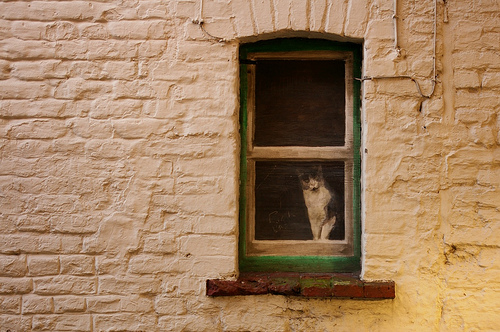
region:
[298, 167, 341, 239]
Gray and white cat in window area.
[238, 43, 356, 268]
Green color framing window.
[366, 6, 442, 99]
Cable cords along side of wall.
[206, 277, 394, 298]
Red bricks under the window.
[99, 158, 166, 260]
Repaired part of brick wall.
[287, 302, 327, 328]
Damage on stone wall.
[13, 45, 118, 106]
Old beige brick wall.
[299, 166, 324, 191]
Cat's face does not look real.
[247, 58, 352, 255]
Beige wooden border frame.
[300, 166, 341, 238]
Cat with gray eyes.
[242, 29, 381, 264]
The window is closed.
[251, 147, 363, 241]
The cat is in the window.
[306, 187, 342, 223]
The cat's fur is black and white.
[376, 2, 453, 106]
Pipes are seen on the outside of building.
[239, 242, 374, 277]
The edge of the window is green.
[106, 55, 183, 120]
Bricks of building have been painted beige.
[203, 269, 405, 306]
The window sill is made out of bricks.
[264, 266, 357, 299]
Bricks have green paint on them.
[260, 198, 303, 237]
The window is scratched.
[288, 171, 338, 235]
cat looking out the window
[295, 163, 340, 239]
gray and white cat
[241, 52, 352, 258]
white frame of the window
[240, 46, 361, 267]
green border around white window frame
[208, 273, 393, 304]
brown ledge under the window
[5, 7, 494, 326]
bricks painted white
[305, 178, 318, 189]
white markings on cat's face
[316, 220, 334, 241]
white leg of the cat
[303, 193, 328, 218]
white chest of the cat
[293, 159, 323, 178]
gray ears of the cat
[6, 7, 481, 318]
a scene in an old building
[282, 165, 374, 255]
a cat in a window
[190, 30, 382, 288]
a window with green trim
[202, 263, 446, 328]
a window sill made of brick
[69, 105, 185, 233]
a wall made of plastered and painted brick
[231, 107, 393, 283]
a painting of a pet looking out the window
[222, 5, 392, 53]
decorative brick around a window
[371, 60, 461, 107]
casing for electrical cords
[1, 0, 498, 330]
A tan painted brick wall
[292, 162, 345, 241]
A black and white cat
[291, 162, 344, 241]
A black and white cat looking out the window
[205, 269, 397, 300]
A red brick window ledge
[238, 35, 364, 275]
A green framed window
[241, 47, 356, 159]
The top pane of a double hung window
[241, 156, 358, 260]
The bottom pane of a double hung window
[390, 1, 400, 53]
A painted piece of conduit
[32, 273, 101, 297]
A single tan painted print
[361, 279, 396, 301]
A single red brick